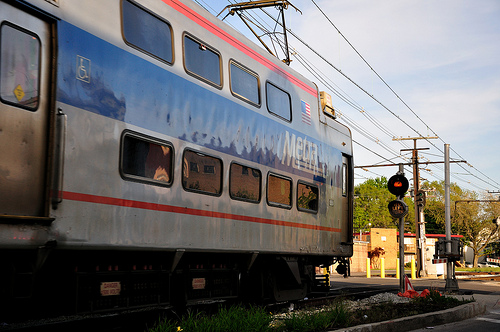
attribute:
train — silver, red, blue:
[0, 0, 359, 257]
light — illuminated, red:
[364, 148, 427, 290]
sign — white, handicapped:
[73, 51, 93, 84]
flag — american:
[299, 99, 318, 126]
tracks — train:
[260, 284, 400, 317]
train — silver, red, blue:
[1, 2, 356, 322]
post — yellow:
[365, 248, 372, 283]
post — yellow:
[379, 253, 386, 281]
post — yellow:
[393, 253, 402, 285]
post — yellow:
[411, 253, 418, 283]